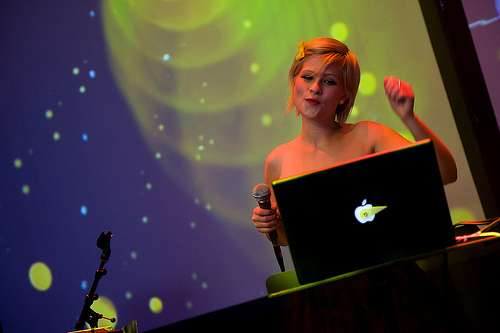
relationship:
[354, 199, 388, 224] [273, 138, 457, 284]
logo on computer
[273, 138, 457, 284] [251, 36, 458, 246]
computer in front of women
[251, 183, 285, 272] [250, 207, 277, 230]
microphone in womans hand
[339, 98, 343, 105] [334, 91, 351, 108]
earring on woman's ear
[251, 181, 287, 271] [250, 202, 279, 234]
microphone held in hand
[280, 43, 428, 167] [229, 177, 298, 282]
woman holding microphone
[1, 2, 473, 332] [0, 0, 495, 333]
lights on wall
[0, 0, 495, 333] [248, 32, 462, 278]
wall behind woman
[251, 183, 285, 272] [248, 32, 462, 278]
microphone held by woman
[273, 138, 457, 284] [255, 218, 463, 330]
computer on table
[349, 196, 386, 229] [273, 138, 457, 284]
logo on computer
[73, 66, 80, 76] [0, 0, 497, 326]
bubble on screen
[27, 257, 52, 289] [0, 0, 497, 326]
bubble on screen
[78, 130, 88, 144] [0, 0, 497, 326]
bubble on screen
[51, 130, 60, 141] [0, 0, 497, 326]
bubble on screen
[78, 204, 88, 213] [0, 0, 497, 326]
bubble on screen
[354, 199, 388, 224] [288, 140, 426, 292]
logo on computer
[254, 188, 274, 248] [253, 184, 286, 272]
hand grasping microphone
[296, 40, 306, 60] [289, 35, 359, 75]
bow in hair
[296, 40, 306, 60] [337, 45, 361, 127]
bow in hair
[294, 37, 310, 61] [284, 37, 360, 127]
bow in hair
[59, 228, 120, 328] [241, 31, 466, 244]
microphone stand next to woman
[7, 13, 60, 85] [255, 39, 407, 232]
wall behind woman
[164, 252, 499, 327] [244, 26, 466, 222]
table in front of woman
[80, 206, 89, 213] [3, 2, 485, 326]
spots are on background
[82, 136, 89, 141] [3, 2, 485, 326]
spots are on background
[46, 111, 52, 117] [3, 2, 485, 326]
spots are on background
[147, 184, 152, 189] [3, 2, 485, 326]
spots are on background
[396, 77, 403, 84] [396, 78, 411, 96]
ring on finger